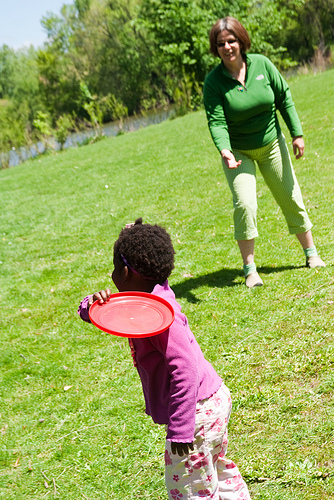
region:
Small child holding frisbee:
[58, 200, 250, 498]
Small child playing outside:
[57, 203, 244, 495]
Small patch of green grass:
[10, 435, 51, 487]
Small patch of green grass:
[62, 448, 91, 498]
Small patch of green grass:
[98, 452, 134, 494]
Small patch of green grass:
[134, 451, 168, 496]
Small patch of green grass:
[246, 455, 275, 493]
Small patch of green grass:
[270, 454, 301, 495]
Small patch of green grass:
[284, 397, 333, 448]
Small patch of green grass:
[237, 374, 277, 433]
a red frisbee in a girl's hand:
[86, 289, 175, 335]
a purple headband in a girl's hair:
[119, 220, 167, 282]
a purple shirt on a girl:
[77, 277, 221, 443]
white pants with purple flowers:
[165, 380, 255, 498]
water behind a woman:
[0, 48, 332, 169]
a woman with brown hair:
[201, 12, 325, 288]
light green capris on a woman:
[222, 135, 317, 238]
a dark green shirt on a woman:
[201, 52, 309, 150]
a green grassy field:
[1, 66, 331, 498]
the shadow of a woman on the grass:
[168, 261, 311, 304]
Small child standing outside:
[57, 210, 259, 495]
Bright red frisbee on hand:
[78, 284, 165, 344]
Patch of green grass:
[19, 462, 73, 495]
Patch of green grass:
[72, 143, 100, 184]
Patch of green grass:
[288, 432, 311, 481]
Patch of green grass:
[242, 411, 262, 452]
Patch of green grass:
[277, 384, 299, 417]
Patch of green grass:
[230, 338, 275, 370]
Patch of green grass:
[281, 331, 315, 362]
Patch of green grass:
[48, 362, 73, 404]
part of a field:
[279, 404, 296, 418]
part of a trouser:
[227, 478, 234, 497]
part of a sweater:
[188, 383, 192, 390]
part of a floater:
[104, 317, 111, 326]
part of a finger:
[104, 290, 109, 294]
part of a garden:
[277, 379, 283, 395]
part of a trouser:
[210, 447, 231, 483]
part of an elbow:
[188, 368, 191, 379]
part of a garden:
[279, 349, 293, 369]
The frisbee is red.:
[81, 283, 167, 341]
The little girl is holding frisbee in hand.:
[78, 215, 208, 380]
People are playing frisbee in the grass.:
[77, 106, 299, 320]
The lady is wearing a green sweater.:
[202, 55, 295, 154]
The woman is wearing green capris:
[220, 149, 309, 225]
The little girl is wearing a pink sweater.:
[122, 340, 227, 405]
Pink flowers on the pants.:
[178, 447, 217, 498]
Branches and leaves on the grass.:
[19, 385, 88, 498]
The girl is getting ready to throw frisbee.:
[76, 278, 179, 346]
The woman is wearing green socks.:
[243, 255, 265, 271]